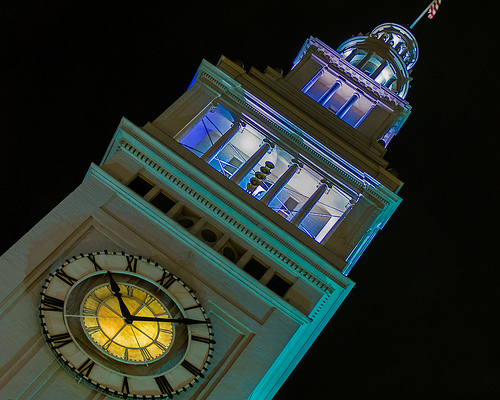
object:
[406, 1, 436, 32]
pole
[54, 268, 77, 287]
roman numeral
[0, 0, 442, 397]
building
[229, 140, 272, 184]
column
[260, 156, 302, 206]
column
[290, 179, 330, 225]
column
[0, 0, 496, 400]
pitch black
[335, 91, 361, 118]
light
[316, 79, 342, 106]
light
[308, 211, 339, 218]
light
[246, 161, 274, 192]
light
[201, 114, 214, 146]
light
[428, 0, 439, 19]
flag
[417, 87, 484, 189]
sky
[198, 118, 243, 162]
column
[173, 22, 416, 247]
lighting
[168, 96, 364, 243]
lit windows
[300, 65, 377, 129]
lit windows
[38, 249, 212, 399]
clock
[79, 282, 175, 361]
face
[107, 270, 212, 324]
hands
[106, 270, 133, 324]
hand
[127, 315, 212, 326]
minute hand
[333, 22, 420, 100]
steeple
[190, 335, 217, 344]
numeral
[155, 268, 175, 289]
numeral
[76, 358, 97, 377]
numeral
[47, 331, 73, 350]
numeral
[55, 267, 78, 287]
numeral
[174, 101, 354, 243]
windows